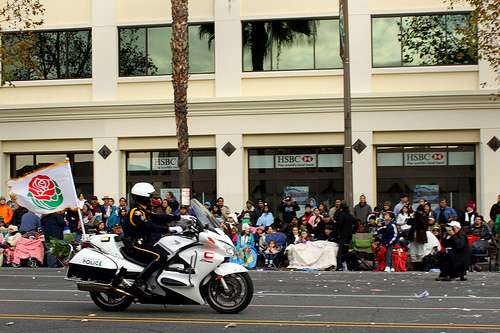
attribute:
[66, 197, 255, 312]
motorcycle — white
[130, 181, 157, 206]
helmet — white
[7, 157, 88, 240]
flag — white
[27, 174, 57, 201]
rose — red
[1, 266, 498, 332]
road — dirty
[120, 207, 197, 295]
uniform — black, blue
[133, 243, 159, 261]
stripe — yellow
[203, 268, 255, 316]
tire — black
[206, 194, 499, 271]
people — watching, standing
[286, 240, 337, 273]
blanket — white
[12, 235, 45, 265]
blanket — pink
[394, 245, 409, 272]
coat — red